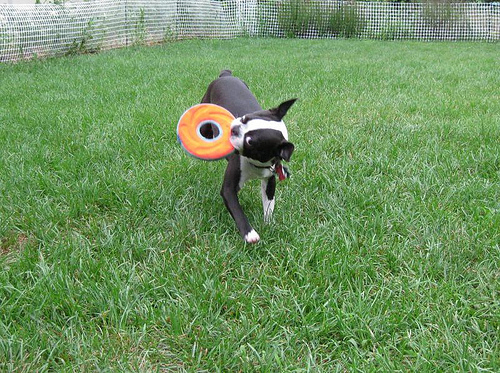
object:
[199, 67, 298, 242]
boston terrier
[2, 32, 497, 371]
grass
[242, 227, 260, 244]
white paw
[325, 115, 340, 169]
wall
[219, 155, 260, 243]
leg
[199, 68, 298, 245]
upper lip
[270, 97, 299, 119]
black ear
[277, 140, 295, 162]
black ear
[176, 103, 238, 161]
disc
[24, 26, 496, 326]
field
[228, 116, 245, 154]
mouth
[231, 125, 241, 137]
nose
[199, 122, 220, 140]
hole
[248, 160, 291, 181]
collar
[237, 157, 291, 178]
neck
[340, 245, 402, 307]
part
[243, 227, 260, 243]
tip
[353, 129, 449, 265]
yard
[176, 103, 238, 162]
ring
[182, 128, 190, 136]
part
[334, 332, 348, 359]
edge